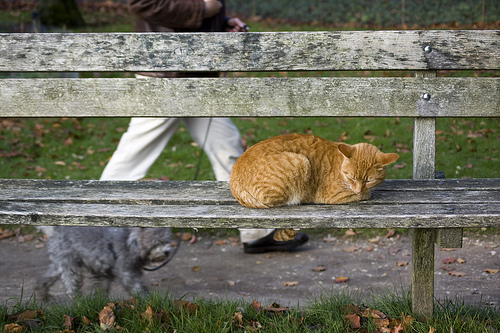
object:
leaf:
[98, 301, 117, 331]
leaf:
[54, 160, 66, 167]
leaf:
[344, 311, 361, 328]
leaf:
[235, 311, 243, 327]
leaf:
[333, 275, 350, 284]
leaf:
[192, 265, 201, 272]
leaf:
[448, 270, 466, 278]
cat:
[230, 133, 399, 209]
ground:
[0, 118, 499, 321]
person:
[97, 1, 311, 254]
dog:
[32, 224, 180, 300]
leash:
[137, 23, 252, 273]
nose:
[163, 250, 170, 256]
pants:
[97, 73, 276, 243]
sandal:
[241, 227, 310, 255]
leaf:
[363, 128, 376, 143]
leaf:
[34, 122, 42, 130]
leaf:
[456, 128, 464, 137]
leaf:
[393, 162, 406, 170]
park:
[1, 2, 499, 330]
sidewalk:
[1, 224, 497, 319]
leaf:
[284, 280, 298, 287]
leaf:
[343, 246, 361, 253]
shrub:
[468, 0, 497, 30]